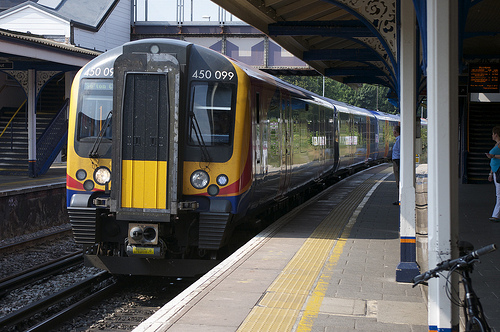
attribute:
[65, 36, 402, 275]
train — yellow, red, blue, back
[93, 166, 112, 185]
light — on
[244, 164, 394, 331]
stripes — yellow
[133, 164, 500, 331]
ground — grey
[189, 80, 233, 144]
window — transparent, glass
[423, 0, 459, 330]
pole — white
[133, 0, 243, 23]
sky — blue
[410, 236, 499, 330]
bike — black, foreground, parked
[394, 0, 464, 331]
posts — support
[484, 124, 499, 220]
woman — standing, on the right, at station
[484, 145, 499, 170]
shirt — blue, teal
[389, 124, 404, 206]
man — waiting, standing, at station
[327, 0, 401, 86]
lattice — decorative, white, blue trimmed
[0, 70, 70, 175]
stairway — at station, blue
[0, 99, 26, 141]
rail — yellow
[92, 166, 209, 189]
haeadlights — large, circles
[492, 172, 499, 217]
pants — white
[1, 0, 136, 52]
building — white